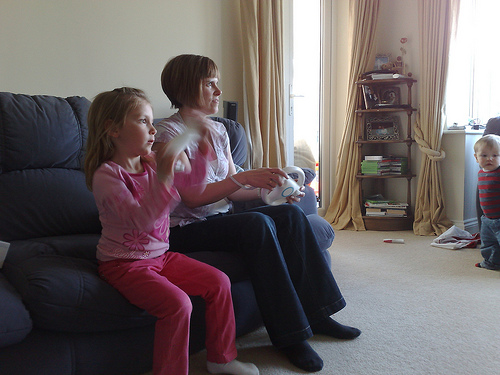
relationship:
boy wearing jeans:
[469, 132, 499, 274] [479, 217, 500, 269]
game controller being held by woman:
[260, 166, 310, 206] [163, 55, 366, 354]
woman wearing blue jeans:
[163, 55, 366, 354] [181, 208, 342, 338]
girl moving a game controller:
[81, 85, 242, 364] [162, 123, 208, 185]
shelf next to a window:
[353, 69, 422, 231] [437, 2, 499, 132]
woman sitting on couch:
[163, 55, 366, 354] [1, 90, 334, 354]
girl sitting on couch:
[81, 85, 242, 364] [1, 90, 334, 354]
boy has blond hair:
[469, 132, 499, 274] [471, 136, 499, 152]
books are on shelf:
[360, 155, 412, 178] [353, 69, 422, 231]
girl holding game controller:
[81, 85, 242, 364] [162, 123, 208, 185]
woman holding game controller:
[163, 55, 366, 354] [260, 166, 310, 206]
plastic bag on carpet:
[429, 224, 482, 256] [345, 244, 476, 335]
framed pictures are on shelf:
[360, 83, 403, 107] [353, 69, 422, 231]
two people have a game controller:
[82, 53, 362, 371] [260, 166, 310, 206]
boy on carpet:
[469, 132, 499, 274] [345, 244, 476, 335]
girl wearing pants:
[81, 85, 242, 364] [106, 252, 242, 375]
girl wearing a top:
[81, 85, 242, 364] [88, 159, 204, 262]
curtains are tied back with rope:
[414, 0, 453, 235] [413, 122, 441, 164]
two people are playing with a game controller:
[82, 53, 362, 371] [260, 166, 310, 206]